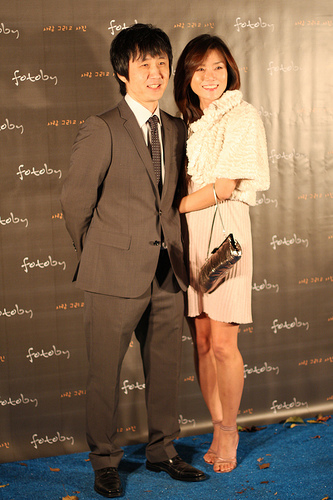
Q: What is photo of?
A: Couple posing.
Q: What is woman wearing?
A: Beige pleated dress.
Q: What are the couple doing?
A: Posing.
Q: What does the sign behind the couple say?
A: Fotoby.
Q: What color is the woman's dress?
A: Cream.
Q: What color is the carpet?
A: Blue.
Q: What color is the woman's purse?
A: Silver.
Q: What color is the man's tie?
A: Black.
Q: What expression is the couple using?
A: Smile.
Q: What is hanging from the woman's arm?
A: Purse.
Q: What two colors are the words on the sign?
A: Orange and white.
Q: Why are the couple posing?
A: To take a picture.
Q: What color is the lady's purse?
A: Silver.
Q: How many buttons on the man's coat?
A: 2.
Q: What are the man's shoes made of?
A: Black leather.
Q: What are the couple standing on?
A: Blue carpet.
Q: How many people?
A: Two.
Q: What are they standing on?
A: Carpet.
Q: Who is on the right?
A: Woman.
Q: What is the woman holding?
A: A handbag.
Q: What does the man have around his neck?
A: Tie.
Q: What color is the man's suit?
A: Brown.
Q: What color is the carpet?
A: Blue.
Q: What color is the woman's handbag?
A: Silver.